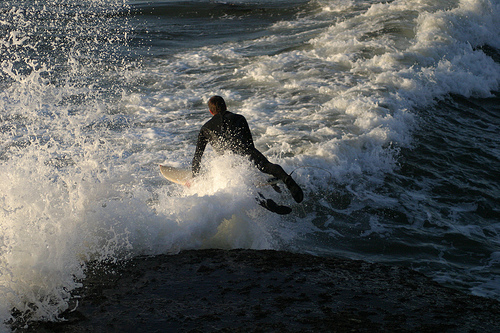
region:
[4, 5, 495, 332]
the water is blue.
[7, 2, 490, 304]
the waves are white.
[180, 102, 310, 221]
man wearing a wetsuit.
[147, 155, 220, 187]
The surfboard is white.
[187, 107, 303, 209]
the wetsuit is black.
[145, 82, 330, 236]
one person is surfing.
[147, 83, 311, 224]
surfboard on the wave.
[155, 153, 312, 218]
man holding a surfboard.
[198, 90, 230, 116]
man's hair is short.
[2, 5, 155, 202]
the water is splashing.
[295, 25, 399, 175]
The water is visible.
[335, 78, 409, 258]
The water is visible.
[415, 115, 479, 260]
The water is visible.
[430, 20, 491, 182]
The water is visible.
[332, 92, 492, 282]
The water is visible.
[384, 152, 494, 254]
The water is visible.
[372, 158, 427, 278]
The water is visible.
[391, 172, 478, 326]
The water is visible.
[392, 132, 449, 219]
The water is visible.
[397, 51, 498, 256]
The water is visible.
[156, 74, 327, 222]
Man in a black wet suit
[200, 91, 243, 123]
Man with brown hair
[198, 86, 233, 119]
Man has wet hair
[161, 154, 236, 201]
Long white surf board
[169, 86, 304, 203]
The man is sitting up on his surfboard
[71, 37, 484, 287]
A large wave of water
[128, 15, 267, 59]
The water is dark blue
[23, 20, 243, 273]
The wave sends up a spray of water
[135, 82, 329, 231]
The man is at the top of the wave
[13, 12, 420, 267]
The water has white spray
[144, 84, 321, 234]
Man surfing in the ocean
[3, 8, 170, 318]
Waves are high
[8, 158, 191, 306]
White water coming out of the ocean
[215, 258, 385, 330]
Ocean is very dark blue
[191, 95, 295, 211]
Man in black bodysuit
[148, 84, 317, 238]
Man looking out towards the sea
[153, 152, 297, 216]
Surfboard is off white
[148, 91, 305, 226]
Man swimming through ocean to surf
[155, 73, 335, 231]
Man surfing the ocean waves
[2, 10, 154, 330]
Ocean waves pounding and spraying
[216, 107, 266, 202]
a black wet suite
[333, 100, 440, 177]
waves in the ocean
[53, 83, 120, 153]
splashes of water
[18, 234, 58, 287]
white splashing water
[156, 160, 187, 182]
surfboard in the water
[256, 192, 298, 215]
a foot of a person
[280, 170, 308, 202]
a foot of a man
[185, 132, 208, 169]
an arm of a person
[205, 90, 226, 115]
a head of a person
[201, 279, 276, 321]
the ocean water